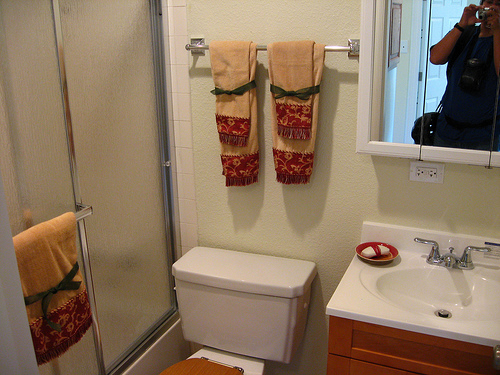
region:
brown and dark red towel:
[269, 41, 324, 184]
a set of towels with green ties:
[207, 38, 326, 189]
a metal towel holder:
[183, 36, 361, 60]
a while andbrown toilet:
[158, 245, 319, 374]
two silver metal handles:
[413, 235, 495, 270]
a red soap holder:
[354, 239, 399, 266]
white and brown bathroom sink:
[325, 220, 498, 373]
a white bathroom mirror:
[355, 63, 499, 170]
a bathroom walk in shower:
[0, 0, 185, 374]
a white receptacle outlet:
[405, 161, 445, 188]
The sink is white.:
[343, 233, 484, 370]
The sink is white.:
[352, 281, 493, 343]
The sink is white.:
[328, 298, 454, 354]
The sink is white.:
[394, 251, 460, 353]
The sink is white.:
[418, 283, 476, 358]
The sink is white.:
[366, 232, 450, 347]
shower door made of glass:
[0, 0, 245, 370]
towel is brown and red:
[205, 31, 345, 220]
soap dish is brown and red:
[339, 226, 403, 276]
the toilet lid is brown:
[156, 340, 237, 373]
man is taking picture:
[384, 1, 496, 142]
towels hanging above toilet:
[206, 27, 356, 187]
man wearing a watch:
[444, 9, 466, 43]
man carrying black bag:
[408, 87, 479, 148]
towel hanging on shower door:
[10, 189, 155, 331]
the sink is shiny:
[372, 254, 497, 336]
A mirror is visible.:
[357, 74, 492, 158]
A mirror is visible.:
[370, 14, 451, 165]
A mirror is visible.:
[380, 48, 464, 109]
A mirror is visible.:
[385, 55, 483, 137]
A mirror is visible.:
[414, 60, 498, 207]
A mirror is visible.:
[417, 17, 475, 181]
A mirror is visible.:
[357, 5, 488, 219]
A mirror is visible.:
[312, 74, 463, 246]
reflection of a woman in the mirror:
[411, 0, 498, 151]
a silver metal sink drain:
[437, 302, 466, 325]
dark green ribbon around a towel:
[268, 77, 317, 103]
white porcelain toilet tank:
[176, 244, 331, 354]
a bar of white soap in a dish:
[360, 233, 404, 273]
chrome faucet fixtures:
[418, 233, 482, 268]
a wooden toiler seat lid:
[178, 355, 228, 374]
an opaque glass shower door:
[71, 4, 137, 204]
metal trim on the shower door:
[56, 42, 69, 97]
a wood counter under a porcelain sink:
[331, 328, 406, 363]